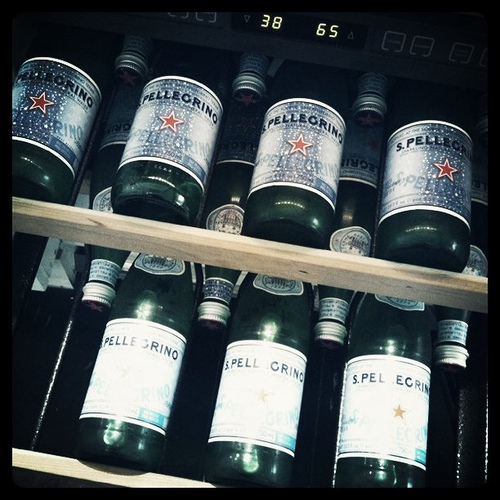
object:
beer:
[110, 44, 227, 226]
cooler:
[12, 13, 487, 488]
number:
[261, 14, 283, 29]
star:
[29, 91, 54, 114]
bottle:
[10, 0, 111, 207]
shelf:
[12, 198, 489, 314]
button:
[382, 29, 407, 53]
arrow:
[347, 32, 354, 40]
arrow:
[243, 14, 250, 22]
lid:
[197, 302, 231, 331]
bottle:
[197, 104, 265, 331]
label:
[12, 57, 102, 181]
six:
[316, 23, 326, 36]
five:
[329, 24, 339, 38]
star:
[159, 111, 184, 133]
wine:
[10, 5, 106, 205]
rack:
[8, 446, 215, 488]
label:
[208, 340, 309, 457]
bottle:
[203, 272, 312, 490]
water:
[75, 251, 196, 474]